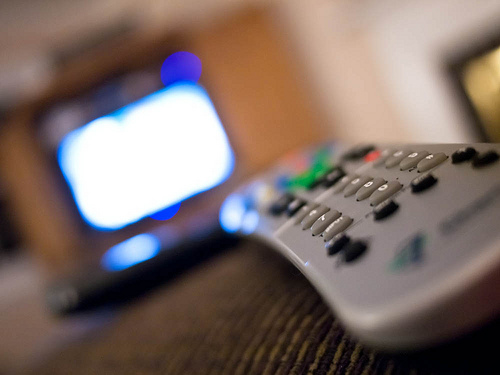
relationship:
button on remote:
[323, 215, 344, 242] [222, 137, 497, 351]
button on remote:
[369, 179, 404, 207] [222, 137, 497, 351]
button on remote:
[406, 152, 444, 173] [222, 137, 497, 351]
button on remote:
[353, 178, 388, 199] [222, 137, 497, 351]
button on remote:
[370, 198, 398, 221] [222, 137, 497, 351]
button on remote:
[322, 231, 354, 252] [222, 137, 497, 351]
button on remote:
[448, 143, 476, 164] [222, 137, 497, 351]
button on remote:
[472, 145, 498, 172] [222, 137, 497, 351]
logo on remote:
[434, 191, 497, 233] [222, 137, 497, 351]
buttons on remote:
[258, 144, 497, 260] [222, 137, 497, 351]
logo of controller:
[387, 231, 425, 265] [219, 134, 498, 348]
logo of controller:
[434, 191, 497, 233] [219, 134, 498, 348]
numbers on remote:
[289, 146, 441, 242] [222, 137, 497, 351]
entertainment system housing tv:
[15, 85, 233, 291] [39, 96, 234, 240]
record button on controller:
[336, 106, 397, 180] [233, 105, 487, 345]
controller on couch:
[219, 134, 498, 348] [37, 264, 441, 373]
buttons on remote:
[317, 137, 442, 245] [282, 105, 434, 363]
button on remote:
[343, 241, 365, 266] [253, 114, 470, 324]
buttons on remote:
[332, 145, 491, 215] [275, 118, 456, 368]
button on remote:
[291, 192, 371, 271] [254, 118, 436, 356]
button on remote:
[339, 144, 404, 218] [275, 118, 456, 368]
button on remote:
[406, 138, 466, 194] [271, 123, 449, 306]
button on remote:
[283, 199, 341, 243] [272, 112, 477, 356]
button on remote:
[335, 176, 399, 217] [275, 118, 456, 368]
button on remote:
[436, 123, 480, 167] [302, 105, 436, 354]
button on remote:
[256, 180, 316, 227] [274, 106, 445, 344]